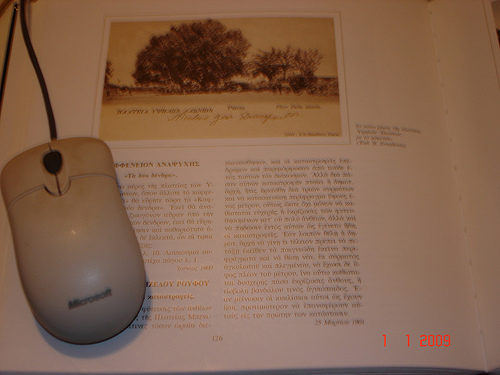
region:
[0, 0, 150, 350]
Computer mouse over a book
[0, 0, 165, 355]
Computer mouse has a wire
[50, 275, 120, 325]
Front of computer mouse has a letter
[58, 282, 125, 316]
Front of computer mouse says "Microsoft"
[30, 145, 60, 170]
Small scroll wheel is black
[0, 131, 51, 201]
Right click button of mouse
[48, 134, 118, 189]
Left click button of mouse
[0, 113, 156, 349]
Mouse is made of plastic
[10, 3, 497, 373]
Open book under computer mouse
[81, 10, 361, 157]
Picture in top of the page of bool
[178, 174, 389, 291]
letters are black in color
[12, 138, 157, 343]
one mouse is seen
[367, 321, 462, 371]
1 1 2009 date is seen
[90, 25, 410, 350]
126th page of book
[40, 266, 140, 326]
microsoft company mouse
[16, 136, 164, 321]
mouse is grey and white in color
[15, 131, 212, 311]
mouse is kept on the book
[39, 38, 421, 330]
night time picture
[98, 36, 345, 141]
one picture is seen in book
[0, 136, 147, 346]
a microsoft mouse on a book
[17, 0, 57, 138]
a black mouse cable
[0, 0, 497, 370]
a page of a book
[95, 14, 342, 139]
a black and white photo with writting on it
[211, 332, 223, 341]
page 126 of a book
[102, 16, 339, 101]
the picture in the book is of trees in a field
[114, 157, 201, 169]
the title of the page is in bold print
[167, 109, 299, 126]
there is hand writing on the photo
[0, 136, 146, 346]
the mouse color is grey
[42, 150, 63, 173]
the scroll wheel is black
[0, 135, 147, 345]
Grey, old computer mouse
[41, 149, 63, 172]
mouse has a dark grey scroll button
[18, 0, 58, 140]
mouse has dark grey cord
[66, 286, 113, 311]
dark grey lettering on mouse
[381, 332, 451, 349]
red date stamp on bottom of image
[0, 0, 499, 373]
open book under mouse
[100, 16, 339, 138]
drawing of trees in book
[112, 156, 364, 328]
text underneath mouse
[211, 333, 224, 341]
page number at bottom of book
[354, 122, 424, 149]
image caption next to drawing of trees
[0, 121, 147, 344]
White, wired computer mouse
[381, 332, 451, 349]
Photo date of 1/1/2009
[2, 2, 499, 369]
Photo of book open to a page with a computer mouse on it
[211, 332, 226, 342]
Book page number 126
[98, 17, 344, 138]
Sepia color book illustration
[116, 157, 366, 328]
Text in page formatted into two columns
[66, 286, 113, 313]
Microsoft name on white computer mouse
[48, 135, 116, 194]
Right button of computer mouse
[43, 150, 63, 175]
Track wheel of computer mouse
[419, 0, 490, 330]
Threaded book binding